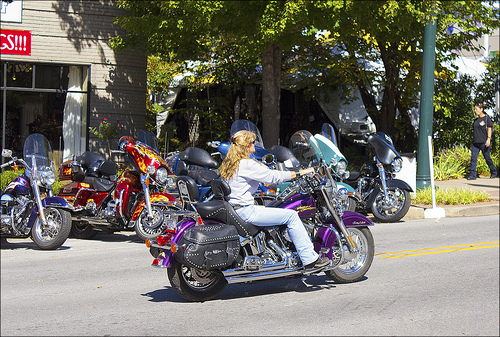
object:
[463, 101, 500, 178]
woman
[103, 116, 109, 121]
rose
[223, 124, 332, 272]
rider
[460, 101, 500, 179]
person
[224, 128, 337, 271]
lady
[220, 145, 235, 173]
tail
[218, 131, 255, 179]
hair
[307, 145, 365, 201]
front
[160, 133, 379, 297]
bike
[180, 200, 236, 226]
saddle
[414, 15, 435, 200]
pole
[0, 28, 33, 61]
sign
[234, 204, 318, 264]
jean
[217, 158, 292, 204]
shirt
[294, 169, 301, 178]
watch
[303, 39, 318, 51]
leave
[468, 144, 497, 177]
short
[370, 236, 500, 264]
line